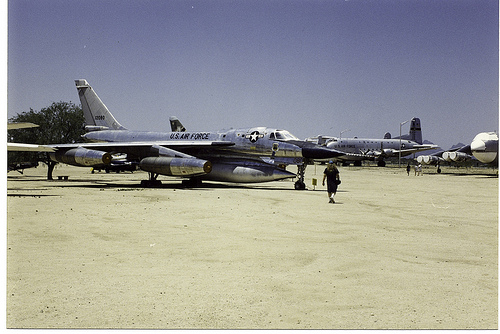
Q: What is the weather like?
A: It is clear.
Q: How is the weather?
A: It is clear.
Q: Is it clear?
A: Yes, it is clear.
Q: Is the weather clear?
A: Yes, it is clear.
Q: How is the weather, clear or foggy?
A: It is clear.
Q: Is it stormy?
A: No, it is clear.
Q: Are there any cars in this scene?
A: No, there are no cars.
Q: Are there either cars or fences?
A: No, there are no cars or fences.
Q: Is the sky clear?
A: Yes, the sky is clear.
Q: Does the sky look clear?
A: Yes, the sky is clear.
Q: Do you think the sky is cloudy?
A: No, the sky is clear.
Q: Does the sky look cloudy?
A: No, the sky is clear.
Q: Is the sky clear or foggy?
A: The sky is clear.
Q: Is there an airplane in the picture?
A: Yes, there is an airplane.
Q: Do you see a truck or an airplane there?
A: Yes, there is an airplane.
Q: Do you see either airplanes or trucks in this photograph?
A: Yes, there is an airplane.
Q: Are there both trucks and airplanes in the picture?
A: No, there is an airplane but no trucks.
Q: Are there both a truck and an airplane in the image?
A: No, there is an airplane but no trucks.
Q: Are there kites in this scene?
A: No, there are no kites.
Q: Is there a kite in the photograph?
A: No, there are no kites.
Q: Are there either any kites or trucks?
A: No, there are no kites or trucks.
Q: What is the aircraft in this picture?
A: The aircraft is an airplane.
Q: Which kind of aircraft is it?
A: The aircraft is an airplane.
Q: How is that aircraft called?
A: This is an airplane.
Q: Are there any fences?
A: No, there are no fences.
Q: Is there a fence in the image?
A: No, there are no fences.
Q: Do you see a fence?
A: No, there are no fences.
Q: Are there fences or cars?
A: No, there are no fences or cars.